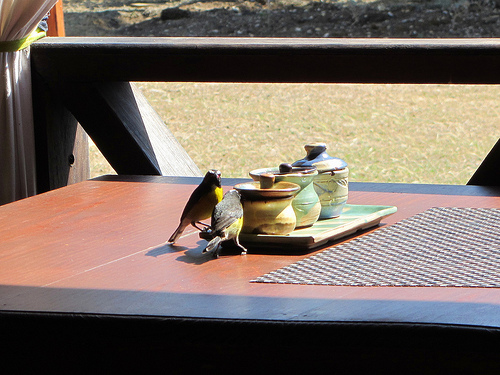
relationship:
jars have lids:
[240, 137, 356, 244] [258, 143, 330, 203]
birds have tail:
[159, 172, 256, 249] [195, 225, 238, 270]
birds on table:
[159, 172, 256, 249] [7, 175, 155, 259]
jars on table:
[240, 137, 356, 244] [7, 175, 155, 259]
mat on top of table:
[239, 195, 496, 289] [7, 175, 155, 259]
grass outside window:
[238, 88, 342, 120] [46, 6, 73, 37]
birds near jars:
[159, 172, 256, 249] [240, 137, 356, 244]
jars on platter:
[240, 137, 356, 244] [294, 197, 382, 248]